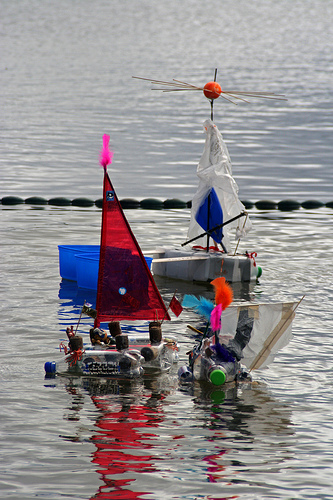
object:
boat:
[53, 140, 171, 380]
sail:
[91, 169, 172, 325]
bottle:
[40, 348, 144, 379]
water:
[1, 1, 331, 498]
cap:
[44, 363, 54, 379]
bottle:
[194, 342, 246, 389]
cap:
[209, 373, 228, 385]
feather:
[100, 137, 109, 168]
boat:
[153, 65, 260, 286]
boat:
[190, 280, 303, 389]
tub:
[57, 245, 130, 283]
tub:
[75, 255, 152, 291]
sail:
[181, 123, 245, 254]